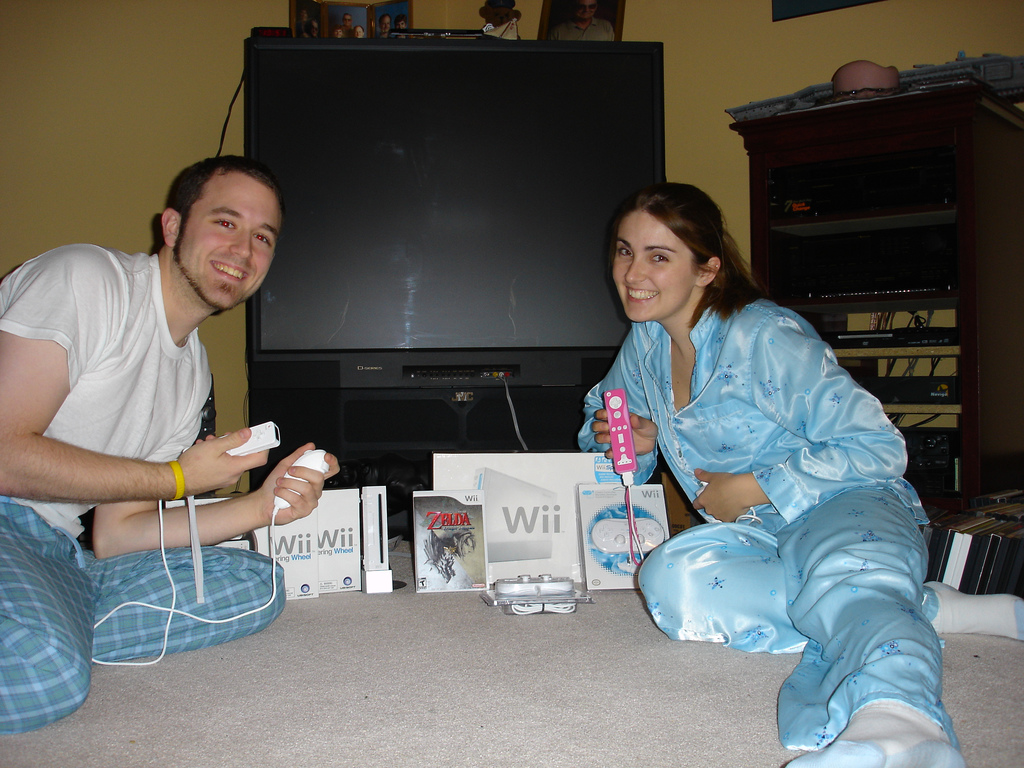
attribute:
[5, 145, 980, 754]
people — gathered, smiling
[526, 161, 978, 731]
woman — smiling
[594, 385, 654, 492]
remote — pink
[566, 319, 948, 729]
pajamas — satin, blue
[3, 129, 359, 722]
man — smiling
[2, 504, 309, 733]
pants — blue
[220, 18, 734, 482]
tv — big, large, projecting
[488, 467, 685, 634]
controllers — white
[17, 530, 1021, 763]
floor — gray, clean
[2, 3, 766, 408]
wall — yellow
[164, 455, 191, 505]
bracelet — yellow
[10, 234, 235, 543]
shirt — white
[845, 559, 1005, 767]
socks — white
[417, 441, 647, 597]
system — boxed